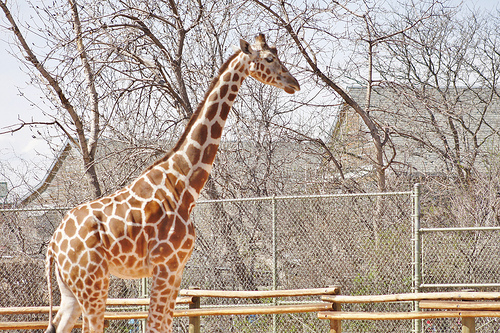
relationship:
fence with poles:
[1, 183, 499, 331] [411, 182, 426, 332]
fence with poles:
[1, 183, 499, 331] [269, 194, 283, 332]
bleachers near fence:
[0, 278, 499, 331] [1, 183, 499, 331]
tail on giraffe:
[41, 248, 60, 332] [32, 22, 308, 332]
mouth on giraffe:
[287, 81, 302, 94] [32, 22, 308, 332]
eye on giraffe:
[263, 53, 279, 69] [32, 22, 308, 332]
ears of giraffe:
[238, 37, 254, 59] [32, 22, 308, 332]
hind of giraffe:
[49, 208, 86, 298] [32, 22, 308, 332]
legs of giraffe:
[143, 266, 171, 332] [32, 22, 308, 332]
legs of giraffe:
[163, 272, 180, 332] [32, 22, 308, 332]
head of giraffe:
[238, 27, 303, 101] [32, 22, 308, 332]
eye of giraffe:
[263, 53, 279, 69] [32, 22, 308, 332]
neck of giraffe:
[175, 69, 252, 195] [32, 22, 308, 332]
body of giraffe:
[41, 172, 198, 282] [32, 22, 308, 332]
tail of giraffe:
[41, 248, 60, 332] [32, 22, 308, 332]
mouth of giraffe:
[287, 81, 302, 94] [32, 22, 308, 332]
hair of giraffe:
[145, 41, 240, 171] [32, 22, 308, 332]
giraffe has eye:
[32, 22, 308, 332] [263, 53, 279, 69]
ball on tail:
[42, 323, 56, 333] [41, 248, 60, 332]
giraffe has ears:
[32, 22, 308, 332] [238, 37, 254, 59]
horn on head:
[251, 31, 270, 47] [238, 27, 303, 101]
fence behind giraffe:
[1, 183, 499, 331] [32, 22, 308, 332]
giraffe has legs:
[32, 22, 308, 332] [143, 266, 171, 332]